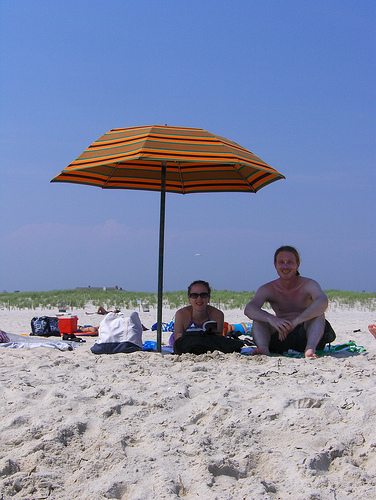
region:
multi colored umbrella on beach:
[58, 106, 284, 198]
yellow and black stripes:
[126, 126, 217, 145]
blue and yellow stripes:
[138, 144, 223, 159]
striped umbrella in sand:
[90, 130, 208, 155]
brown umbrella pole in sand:
[139, 160, 171, 364]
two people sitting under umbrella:
[147, 237, 342, 350]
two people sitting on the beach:
[180, 228, 356, 351]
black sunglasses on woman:
[181, 289, 213, 302]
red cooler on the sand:
[56, 312, 82, 336]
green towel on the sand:
[344, 339, 362, 359]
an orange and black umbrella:
[49, 96, 297, 223]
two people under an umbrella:
[155, 244, 341, 347]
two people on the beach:
[161, 228, 373, 390]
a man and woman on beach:
[162, 221, 357, 374]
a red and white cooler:
[50, 298, 81, 338]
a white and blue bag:
[84, 299, 148, 362]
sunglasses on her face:
[184, 288, 209, 304]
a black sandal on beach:
[60, 326, 106, 351]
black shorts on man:
[234, 304, 343, 368]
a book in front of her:
[171, 316, 240, 341]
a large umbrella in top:
[68, 95, 287, 202]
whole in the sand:
[201, 441, 254, 491]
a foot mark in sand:
[205, 443, 257, 494]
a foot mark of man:
[98, 413, 160, 485]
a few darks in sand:
[22, 406, 259, 498]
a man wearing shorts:
[241, 298, 365, 365]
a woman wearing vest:
[162, 289, 235, 359]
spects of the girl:
[186, 281, 217, 298]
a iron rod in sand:
[147, 172, 168, 368]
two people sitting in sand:
[131, 252, 329, 350]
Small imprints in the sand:
[13, 441, 65, 495]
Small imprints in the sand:
[49, 412, 90, 461]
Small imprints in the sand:
[99, 398, 134, 424]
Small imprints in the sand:
[203, 453, 245, 494]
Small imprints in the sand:
[309, 439, 348, 478]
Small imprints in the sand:
[284, 361, 311, 421]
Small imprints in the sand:
[11, 366, 47, 408]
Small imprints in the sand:
[99, 476, 139, 495]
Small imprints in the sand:
[126, 451, 178, 498]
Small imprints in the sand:
[132, 397, 187, 439]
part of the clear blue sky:
[0, 8, 53, 43]